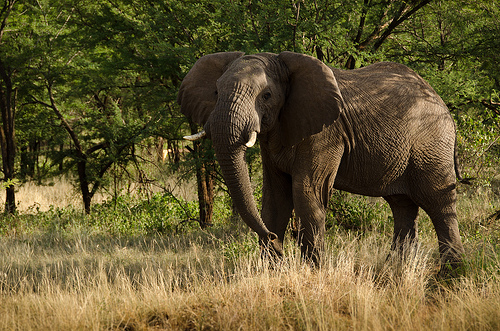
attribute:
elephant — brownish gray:
[177, 42, 474, 282]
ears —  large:
[260, 42, 341, 123]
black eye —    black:
[262, 91, 273, 103]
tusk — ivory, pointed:
[174, 127, 194, 144]